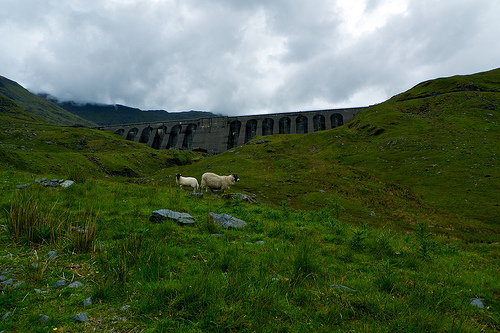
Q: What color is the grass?
A: Green.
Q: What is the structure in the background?
A: Bridge.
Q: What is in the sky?
A: Gray clouds.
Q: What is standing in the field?
A: Two sheep.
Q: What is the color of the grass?
A: Green.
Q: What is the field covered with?
A: Grasses.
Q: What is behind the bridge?
A: Mountains.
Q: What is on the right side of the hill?
A: Green grass.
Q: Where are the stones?
A: On the green grass.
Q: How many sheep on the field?
A: Two.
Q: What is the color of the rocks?
A: Gray.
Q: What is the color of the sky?
A: Gray.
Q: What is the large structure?
A: Bridge.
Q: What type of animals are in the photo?
A: Sheep.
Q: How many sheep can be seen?
A: 2.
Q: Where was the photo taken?
A: In a field.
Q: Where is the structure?
A: Behind the sheep.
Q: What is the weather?
A: Cloudy.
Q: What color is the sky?
A: Gray.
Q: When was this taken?
A: Daytime.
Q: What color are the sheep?
A: White and black.